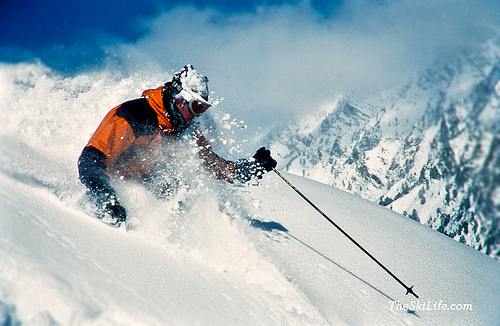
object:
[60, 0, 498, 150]
fog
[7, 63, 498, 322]
snow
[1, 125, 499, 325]
mountain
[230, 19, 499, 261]
mountain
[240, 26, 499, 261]
snow